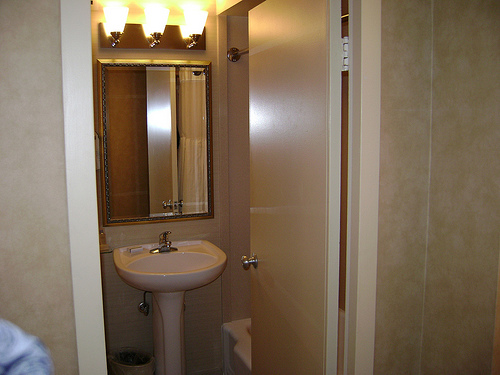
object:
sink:
[111, 239, 228, 375]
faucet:
[149, 230, 178, 254]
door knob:
[240, 252, 258, 270]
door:
[240, 0, 343, 375]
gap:
[335, 0, 351, 374]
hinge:
[341, 37, 350, 72]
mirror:
[96, 58, 215, 227]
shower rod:
[226, 12, 348, 63]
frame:
[342, 0, 382, 375]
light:
[182, 8, 210, 49]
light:
[142, 6, 171, 48]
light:
[101, 4, 130, 47]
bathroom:
[92, 0, 347, 375]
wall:
[90, 12, 232, 375]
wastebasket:
[106, 344, 157, 375]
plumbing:
[138, 291, 150, 316]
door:
[145, 65, 185, 219]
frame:
[95, 57, 216, 227]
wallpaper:
[370, 0, 500, 375]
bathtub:
[220, 306, 346, 375]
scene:
[0, 0, 500, 375]